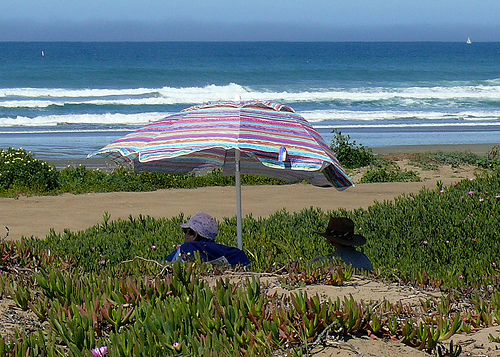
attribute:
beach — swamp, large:
[2, 136, 495, 348]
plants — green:
[0, 132, 422, 189]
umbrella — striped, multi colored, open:
[93, 98, 355, 276]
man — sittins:
[300, 214, 375, 281]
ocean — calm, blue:
[5, 4, 499, 129]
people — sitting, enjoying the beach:
[162, 209, 374, 281]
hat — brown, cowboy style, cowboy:
[315, 213, 367, 251]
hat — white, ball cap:
[184, 211, 223, 240]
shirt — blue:
[167, 242, 247, 267]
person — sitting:
[168, 213, 248, 269]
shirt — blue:
[315, 248, 373, 275]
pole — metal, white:
[233, 148, 249, 261]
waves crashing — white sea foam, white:
[3, 82, 498, 137]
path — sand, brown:
[5, 185, 433, 239]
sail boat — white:
[462, 33, 474, 45]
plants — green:
[2, 174, 499, 352]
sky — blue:
[3, 4, 499, 45]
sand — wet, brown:
[3, 132, 497, 157]